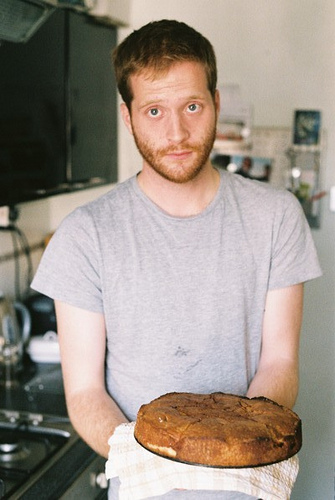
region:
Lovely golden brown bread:
[134, 367, 314, 482]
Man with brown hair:
[100, 6, 226, 194]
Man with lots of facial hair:
[102, 20, 218, 190]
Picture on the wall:
[286, 103, 330, 153]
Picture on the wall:
[283, 141, 327, 226]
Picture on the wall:
[228, 151, 283, 185]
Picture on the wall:
[220, 114, 256, 150]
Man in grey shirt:
[47, 23, 309, 469]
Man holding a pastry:
[32, 7, 303, 497]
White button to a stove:
[88, 467, 104, 486]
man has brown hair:
[101, 18, 215, 86]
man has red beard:
[123, 74, 217, 204]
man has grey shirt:
[54, 170, 334, 349]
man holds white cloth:
[94, 403, 311, 497]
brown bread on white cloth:
[162, 383, 333, 471]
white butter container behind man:
[27, 299, 71, 384]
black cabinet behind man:
[1, 2, 119, 184]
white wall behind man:
[177, 14, 320, 105]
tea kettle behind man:
[1, 290, 37, 373]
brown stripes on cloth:
[99, 420, 277, 497]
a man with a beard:
[113, 11, 223, 185]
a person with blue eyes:
[140, 96, 203, 121]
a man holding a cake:
[26, 18, 330, 498]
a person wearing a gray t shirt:
[19, 10, 331, 499]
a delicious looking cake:
[133, 387, 307, 461]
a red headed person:
[105, 18, 224, 181]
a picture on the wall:
[290, 103, 322, 151]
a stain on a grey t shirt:
[168, 340, 200, 372]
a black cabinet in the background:
[0, 0, 126, 206]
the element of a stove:
[0, 433, 46, 475]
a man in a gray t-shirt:
[28, 17, 322, 497]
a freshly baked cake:
[132, 389, 303, 469]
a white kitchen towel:
[103, 421, 301, 499]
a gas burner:
[1, 419, 66, 477]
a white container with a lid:
[27, 329, 65, 366]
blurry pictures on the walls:
[211, 97, 322, 185]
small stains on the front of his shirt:
[169, 342, 206, 382]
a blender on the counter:
[0, 291, 38, 388]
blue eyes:
[141, 97, 203, 119]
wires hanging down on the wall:
[0, 202, 35, 301]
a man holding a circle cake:
[41, 30, 332, 488]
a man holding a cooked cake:
[76, 52, 333, 471]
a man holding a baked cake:
[33, 78, 331, 436]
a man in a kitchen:
[3, 3, 332, 374]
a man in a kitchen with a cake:
[8, 17, 294, 496]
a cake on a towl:
[82, 381, 289, 498]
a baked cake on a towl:
[97, 360, 283, 498]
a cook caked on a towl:
[58, 371, 334, 474]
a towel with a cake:
[51, 372, 240, 495]